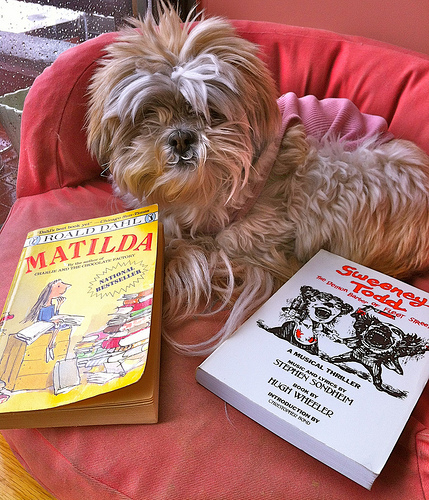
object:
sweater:
[233, 90, 394, 232]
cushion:
[0, 180, 428, 498]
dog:
[80, 0, 428, 357]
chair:
[0, 18, 428, 498]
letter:
[48, 245, 68, 266]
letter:
[67, 240, 86, 260]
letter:
[85, 237, 100, 256]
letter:
[97, 235, 117, 254]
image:
[256, 284, 428, 399]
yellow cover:
[0, 199, 159, 414]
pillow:
[1, 172, 429, 500]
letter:
[23, 251, 48, 274]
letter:
[115, 233, 138, 254]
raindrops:
[0, 0, 133, 229]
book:
[194, 246, 428, 492]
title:
[198, 245, 429, 475]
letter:
[336, 264, 356, 277]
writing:
[336, 261, 429, 316]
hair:
[80, 0, 283, 209]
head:
[79, 0, 281, 223]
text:
[19, 232, 156, 271]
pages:
[22, 208, 159, 273]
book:
[0, 202, 165, 430]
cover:
[0, 202, 166, 428]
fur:
[217, 147, 400, 246]